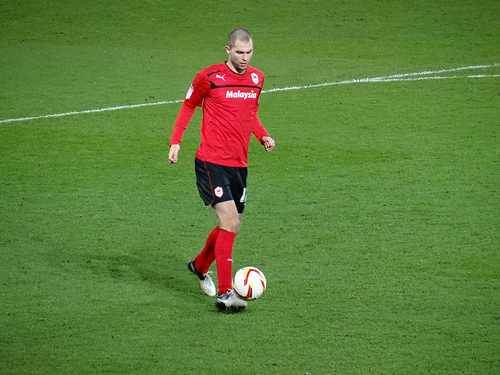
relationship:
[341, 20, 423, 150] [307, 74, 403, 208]
green soccer field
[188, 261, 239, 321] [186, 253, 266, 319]
gray and black shoes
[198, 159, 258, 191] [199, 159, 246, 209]
black shorts with pinstripe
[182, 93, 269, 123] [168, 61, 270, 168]
red long sleeve red shirt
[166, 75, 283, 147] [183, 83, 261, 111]
name of team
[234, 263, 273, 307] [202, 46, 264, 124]
white chalk lines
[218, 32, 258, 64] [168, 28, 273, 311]
head of man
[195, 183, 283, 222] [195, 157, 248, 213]
logo on black shorts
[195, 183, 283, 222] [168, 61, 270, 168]
logo on red shirt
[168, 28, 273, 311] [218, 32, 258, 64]
man has short hair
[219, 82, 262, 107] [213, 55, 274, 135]
white puma on jersey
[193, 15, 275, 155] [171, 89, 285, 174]
mean wearing red shirt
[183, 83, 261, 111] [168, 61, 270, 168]
writing on red shirt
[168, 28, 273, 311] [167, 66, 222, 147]
man wearing sleeves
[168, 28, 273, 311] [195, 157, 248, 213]
man wearing black shorts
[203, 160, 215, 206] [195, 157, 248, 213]
pinstripe down black shorts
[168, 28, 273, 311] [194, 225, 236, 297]
man wearing long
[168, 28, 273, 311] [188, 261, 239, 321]
man wearing shoes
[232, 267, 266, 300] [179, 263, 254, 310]
ball ball on feet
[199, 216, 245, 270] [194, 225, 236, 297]
long red long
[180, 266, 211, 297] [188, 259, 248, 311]
black soccer black shoes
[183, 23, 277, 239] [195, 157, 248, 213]
man black black shorts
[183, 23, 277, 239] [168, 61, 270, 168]
man red red shirt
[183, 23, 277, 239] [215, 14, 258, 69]
man short hair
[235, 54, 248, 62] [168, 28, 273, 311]
nose of man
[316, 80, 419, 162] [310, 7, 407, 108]
section of grass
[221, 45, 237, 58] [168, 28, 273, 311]
ear of man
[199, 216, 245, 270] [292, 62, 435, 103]
long white line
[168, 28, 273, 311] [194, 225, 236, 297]
man with long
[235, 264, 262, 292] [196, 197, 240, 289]
ball near legs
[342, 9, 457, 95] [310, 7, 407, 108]
play ground of grass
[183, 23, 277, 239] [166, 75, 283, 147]
person wearing t-shirt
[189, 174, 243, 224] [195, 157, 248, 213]
symbol on black shorts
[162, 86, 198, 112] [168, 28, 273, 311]
elbow of man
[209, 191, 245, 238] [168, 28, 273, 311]
knee of man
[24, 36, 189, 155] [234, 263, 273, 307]
ground marked white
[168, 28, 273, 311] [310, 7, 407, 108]
man on grass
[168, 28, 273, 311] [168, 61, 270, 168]
man wearing red shirt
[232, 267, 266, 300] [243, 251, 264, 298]
ball ball white,red,yellow